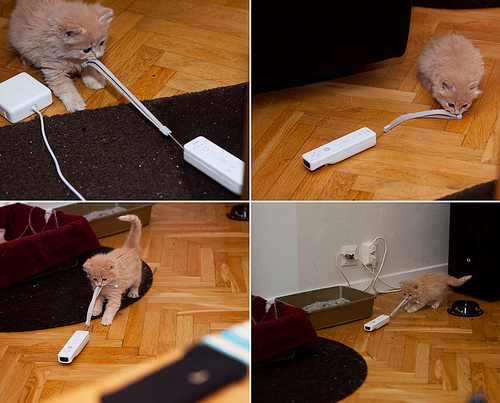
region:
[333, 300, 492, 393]
herring bone design in wood floor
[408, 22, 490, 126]
tan kitten play with video game controller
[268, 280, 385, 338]
green cat box on wooden floor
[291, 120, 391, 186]
video game controller on wooden floor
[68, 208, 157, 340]
tan kitten with strap of video game controller in its mouth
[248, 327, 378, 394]
black oval throw rug on floor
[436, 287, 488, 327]
silver cat bowl on a wooden floor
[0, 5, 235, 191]
tan kitten pulling video game controller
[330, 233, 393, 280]
white plugs in electrical outlet on wall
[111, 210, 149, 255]
tail of tan kitten playing with controller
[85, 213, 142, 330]
orange kitten with a strap in its mouth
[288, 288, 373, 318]
cat litter box on the floor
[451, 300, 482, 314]
silver pet food bowl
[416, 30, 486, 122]
orange kitten chewing on the strap of a wii controller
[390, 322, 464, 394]
parquet wood floor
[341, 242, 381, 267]
electrical outlets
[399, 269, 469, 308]
crouching orange kitten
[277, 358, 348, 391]
black rug on the floor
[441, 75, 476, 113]
orange kitten's face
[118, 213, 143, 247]
orange kitten's tail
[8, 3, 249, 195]
A cat with a wii controller in it's mouth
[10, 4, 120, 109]
An orange kitty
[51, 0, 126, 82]
Kitten holds Wii cord in it's mouth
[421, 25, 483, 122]
Kitten bites on Wii cord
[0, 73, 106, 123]
A kitten's paw next to an Apple battery pack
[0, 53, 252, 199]
A black carpet on a wooden floor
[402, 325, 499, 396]
The wooden floor has a zig zag pattern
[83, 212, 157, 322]
A cat with it's tail in the air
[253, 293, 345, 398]
A red box on top of a black carpet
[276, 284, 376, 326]
The litter box is against the wall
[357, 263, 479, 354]
the cat has the controller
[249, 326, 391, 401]
the rug is black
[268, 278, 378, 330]
the cat box is dirty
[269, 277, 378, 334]
the litter box is brown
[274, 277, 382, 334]
the litter is in the box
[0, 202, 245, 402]
the floor is parquet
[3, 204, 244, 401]
the floor is wood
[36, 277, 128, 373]
the controller is white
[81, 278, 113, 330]
the controller has a strap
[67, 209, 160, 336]
the kitten is playing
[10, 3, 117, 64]
A cat sitting on the floor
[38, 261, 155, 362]
A cat is playing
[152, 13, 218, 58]
Wooden type floor tiles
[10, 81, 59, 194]
Wire attached in the electronic device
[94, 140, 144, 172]
Black color carpet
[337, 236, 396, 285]
Electric board with wires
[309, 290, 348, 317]
A brown color plastic tray kept near the wall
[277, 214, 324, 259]
White color wall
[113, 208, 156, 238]
Tail of the cat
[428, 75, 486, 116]
Head of the cat